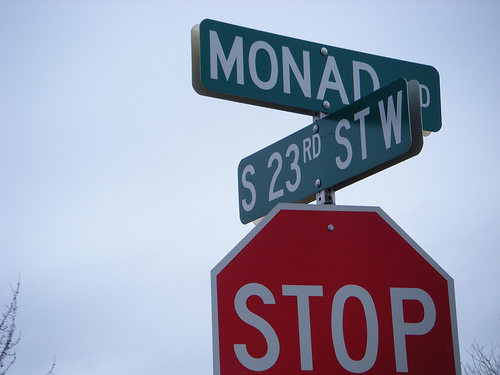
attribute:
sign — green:
[236, 78, 425, 227]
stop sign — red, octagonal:
[209, 202, 462, 374]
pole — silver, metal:
[314, 110, 337, 206]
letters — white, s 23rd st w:
[241, 89, 404, 211]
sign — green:
[189, 17, 442, 136]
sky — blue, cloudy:
[2, 1, 500, 374]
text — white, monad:
[210, 29, 432, 108]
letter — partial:
[352, 58, 381, 103]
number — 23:
[267, 143, 302, 202]